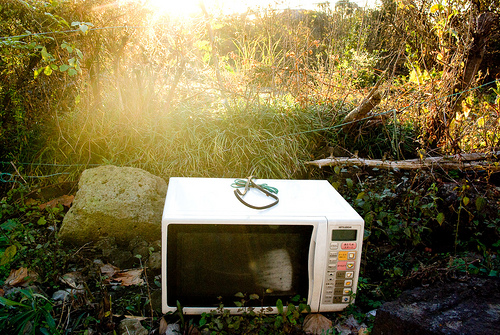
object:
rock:
[56, 166, 166, 242]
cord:
[227, 174, 281, 211]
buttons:
[343, 241, 356, 250]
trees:
[413, 1, 492, 147]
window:
[164, 224, 315, 311]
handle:
[306, 220, 331, 314]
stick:
[300, 151, 497, 177]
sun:
[110, 0, 379, 104]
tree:
[292, 146, 495, 177]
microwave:
[157, 171, 364, 316]